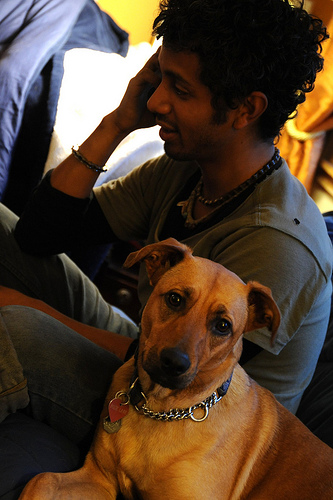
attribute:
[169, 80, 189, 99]
eye — man's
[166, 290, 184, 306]
eye — sad, brown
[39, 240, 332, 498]
nose — black, shiny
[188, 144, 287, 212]
necklace — black, beaded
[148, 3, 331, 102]
hair — curly, black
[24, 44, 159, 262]
arm — man's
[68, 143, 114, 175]
wrist band — black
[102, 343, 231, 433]
collar — chain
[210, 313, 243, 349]
eye — dog's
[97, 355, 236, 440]
collar — chain link, dog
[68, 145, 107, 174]
bracelet — beaded, black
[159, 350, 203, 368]
nose — black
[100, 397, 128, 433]
dog tags — red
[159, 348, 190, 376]
nose — black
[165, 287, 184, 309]
eye — small, black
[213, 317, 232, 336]
eye — black, small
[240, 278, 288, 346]
ear — floppy, brown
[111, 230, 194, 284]
ear — floppy, brown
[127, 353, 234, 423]
collar — chain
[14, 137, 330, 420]
shirt — blue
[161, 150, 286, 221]
necklace — black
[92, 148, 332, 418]
t-shirt — blue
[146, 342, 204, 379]
nose — black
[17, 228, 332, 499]
dog — brown, furry, large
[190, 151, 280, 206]
necklace — black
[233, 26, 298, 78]
hair — dark, brown, curly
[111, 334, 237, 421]
collar — dog's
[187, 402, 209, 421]
loop — metal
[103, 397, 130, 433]
dog tags — metal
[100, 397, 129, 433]
tag — small, red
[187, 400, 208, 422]
ring — silver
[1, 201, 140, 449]
jeans — blue